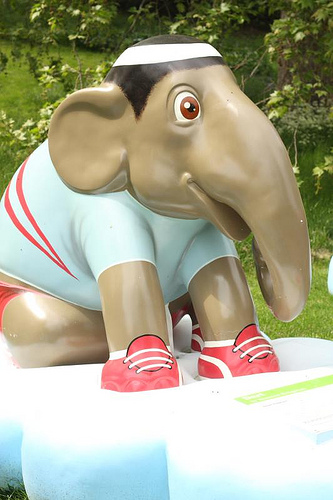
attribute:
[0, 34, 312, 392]
elephant — gray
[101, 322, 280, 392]
shoes — red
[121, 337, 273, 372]
shoelaces — white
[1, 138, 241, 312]
shirt — blue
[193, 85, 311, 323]
trunk — gray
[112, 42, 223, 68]
headband — white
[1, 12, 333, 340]
grass — green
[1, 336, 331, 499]
platform — blue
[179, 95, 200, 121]
eye — brown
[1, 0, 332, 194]
leaves — green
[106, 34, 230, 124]
hair — black